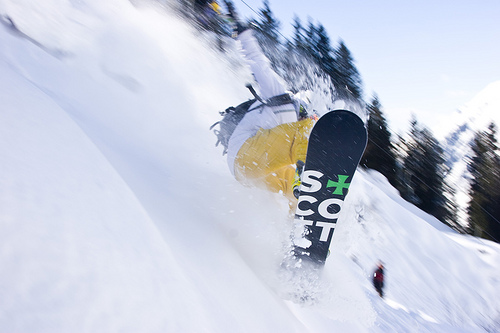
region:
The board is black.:
[289, 106, 347, 270]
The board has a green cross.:
[322, 168, 349, 200]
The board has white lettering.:
[286, 168, 353, 265]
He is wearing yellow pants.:
[245, 119, 312, 206]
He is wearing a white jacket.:
[216, 93, 298, 143]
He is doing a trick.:
[213, 3, 374, 285]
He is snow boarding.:
[205, 6, 368, 286]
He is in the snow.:
[367, 256, 389, 301]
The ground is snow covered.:
[38, 24, 243, 331]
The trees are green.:
[187, 1, 492, 236]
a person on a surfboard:
[140, 11, 422, 287]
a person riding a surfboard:
[182, 10, 439, 269]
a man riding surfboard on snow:
[129, 21, 441, 323]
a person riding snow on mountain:
[128, 37, 411, 312]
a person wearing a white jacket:
[72, 7, 362, 327]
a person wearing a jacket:
[180, 20, 381, 245]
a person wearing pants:
[187, 47, 407, 266]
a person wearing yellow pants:
[172, 18, 415, 234]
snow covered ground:
[36, 129, 200, 331]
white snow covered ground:
[4, 146, 127, 307]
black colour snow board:
[278, 105, 389, 286]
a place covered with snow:
[74, 65, 192, 297]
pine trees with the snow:
[403, 117, 497, 242]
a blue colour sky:
[401, 24, 466, 66]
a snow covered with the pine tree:
[446, 115, 479, 180]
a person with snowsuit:
[208, 27, 288, 206]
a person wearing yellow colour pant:
[231, 107, 345, 199]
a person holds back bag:
[215, 78, 308, 155]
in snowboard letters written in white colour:
[289, 146, 344, 286]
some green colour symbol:
[322, 171, 350, 197]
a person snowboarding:
[151, 32, 393, 258]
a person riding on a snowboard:
[202, 67, 458, 304]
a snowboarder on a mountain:
[69, 27, 468, 327]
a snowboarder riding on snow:
[78, 9, 450, 317]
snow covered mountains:
[19, 71, 266, 321]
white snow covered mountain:
[22, 91, 233, 306]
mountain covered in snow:
[8, 77, 253, 309]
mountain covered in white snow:
[39, 86, 204, 294]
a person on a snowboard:
[164, 9, 464, 316]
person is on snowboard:
[205, 71, 357, 228]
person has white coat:
[226, 103, 287, 145]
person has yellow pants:
[209, 125, 317, 186]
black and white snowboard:
[281, 103, 379, 282]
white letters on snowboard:
[282, 161, 362, 277]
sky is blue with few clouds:
[377, 25, 494, 103]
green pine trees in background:
[297, 26, 489, 216]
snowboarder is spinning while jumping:
[212, 96, 362, 235]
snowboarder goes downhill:
[59, 25, 391, 301]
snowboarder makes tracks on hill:
[207, 79, 407, 307]